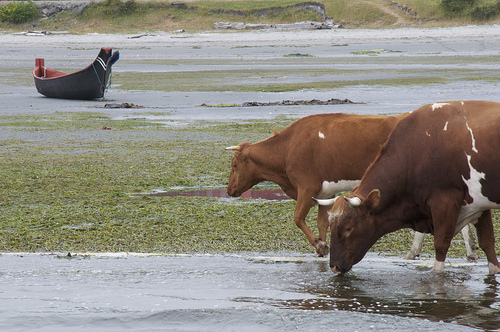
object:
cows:
[225, 100, 500, 276]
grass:
[0, 110, 499, 259]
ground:
[0, 0, 500, 331]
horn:
[226, 145, 240, 151]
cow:
[311, 99, 500, 275]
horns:
[312, 196, 362, 208]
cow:
[225, 112, 472, 261]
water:
[0, 23, 498, 331]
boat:
[33, 46, 120, 100]